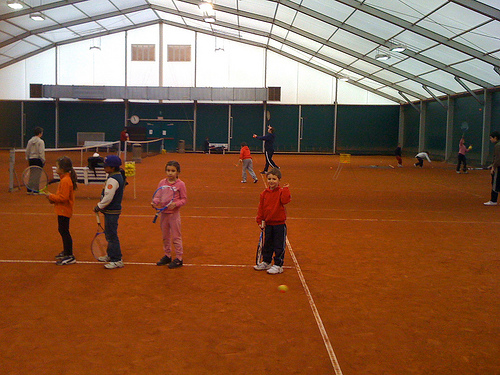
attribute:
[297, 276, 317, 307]
line — white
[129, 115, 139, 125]
clock — white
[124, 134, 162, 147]
trim — white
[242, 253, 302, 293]
shoes — white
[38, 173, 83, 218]
sweatshirt — orange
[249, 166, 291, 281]
boy — red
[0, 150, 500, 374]
tennis court — orange colored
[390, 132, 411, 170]
child — playing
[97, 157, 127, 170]
cap — blue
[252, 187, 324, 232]
sweater — red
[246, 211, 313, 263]
sweatpants — blue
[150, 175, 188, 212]
sweater — pink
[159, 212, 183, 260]
pants — pink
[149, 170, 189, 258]
outfit — pink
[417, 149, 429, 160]
top — white